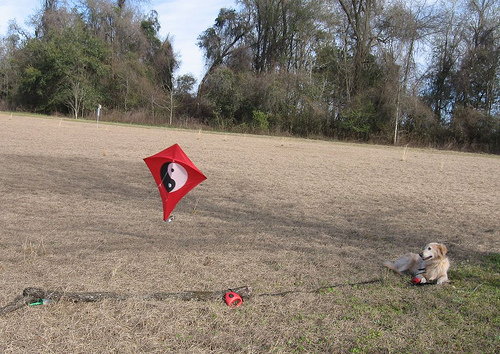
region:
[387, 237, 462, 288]
Dog on the grass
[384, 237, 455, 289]
Dog is on the grass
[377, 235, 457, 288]
Dog laying down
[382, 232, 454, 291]
Dog is laying down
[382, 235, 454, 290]
Dog laying down on the grass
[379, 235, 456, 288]
Dog is laying down on the grass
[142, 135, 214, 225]
Kite in the air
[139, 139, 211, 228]
Red kite is in the air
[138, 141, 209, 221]
red kite with a yin yang symbol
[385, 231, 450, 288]
golden retreiver on the ground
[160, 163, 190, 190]
yin yang symbol on a kite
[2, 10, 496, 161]
tall trees in the background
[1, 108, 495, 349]
large field with dormant grass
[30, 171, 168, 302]
kite string attached diagonally to the ground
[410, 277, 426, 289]
a red ball by the dog's foot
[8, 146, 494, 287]
shadow of a tree casted on the ground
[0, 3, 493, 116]
blue sky behind the trees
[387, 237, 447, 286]
the dog is looking at the kite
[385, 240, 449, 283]
the dog lying down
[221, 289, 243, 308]
the handle for the dog's leash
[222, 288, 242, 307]
the red handle for the leash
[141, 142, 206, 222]
the red kite in mid air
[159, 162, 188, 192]
the black and white design on the kite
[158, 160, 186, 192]
the ying and yang sign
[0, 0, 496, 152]
the brown and bare in the background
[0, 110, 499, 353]
the short brown grass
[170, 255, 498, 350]
the small area of green on the grass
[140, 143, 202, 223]
The kite is red.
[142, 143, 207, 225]
The kite has a ying yang.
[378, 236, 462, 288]
The dog is a golden retriever.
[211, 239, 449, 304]
The dog is on a leash.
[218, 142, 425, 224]
The grass is dead.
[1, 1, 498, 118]
It appears to be a nice day.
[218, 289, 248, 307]
The leash handle is red.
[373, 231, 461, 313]
blonde long haired golden retriever in grass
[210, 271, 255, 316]
red and black plastic handle of leash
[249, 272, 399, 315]
long black fabric leash laying in field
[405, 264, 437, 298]
red plastic toy next to dog's foot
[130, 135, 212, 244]
kite sitting on the ground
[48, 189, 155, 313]
thin string holding the kite down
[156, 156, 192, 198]
black and white design on the kite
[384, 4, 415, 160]
A tree in a field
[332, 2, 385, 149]
A tree in a field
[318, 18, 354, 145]
A tree in a field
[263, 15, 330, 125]
A tree in a field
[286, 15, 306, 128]
A tree in a field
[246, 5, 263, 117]
A tree in a field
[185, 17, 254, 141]
A tree in a field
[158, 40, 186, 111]
A tree in a field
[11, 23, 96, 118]
A tree in a field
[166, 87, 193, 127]
A tree in a field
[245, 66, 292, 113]
green leaves on the tree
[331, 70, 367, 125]
green leaves on the tree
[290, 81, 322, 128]
green leaves on the tree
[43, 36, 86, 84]
green leaves on the tree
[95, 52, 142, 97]
green leaves on the tree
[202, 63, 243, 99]
green leaves on the tree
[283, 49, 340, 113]
green leaves on the tree